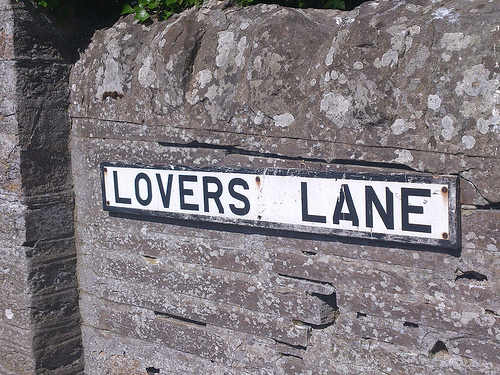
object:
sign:
[100, 161, 460, 250]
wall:
[66, 0, 499, 374]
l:
[109, 167, 135, 205]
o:
[133, 170, 155, 208]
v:
[153, 172, 177, 210]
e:
[176, 172, 202, 212]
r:
[199, 174, 226, 215]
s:
[225, 174, 251, 217]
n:
[364, 184, 397, 232]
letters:
[112, 170, 252, 214]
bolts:
[252, 174, 264, 183]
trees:
[114, 0, 211, 20]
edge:
[103, 161, 139, 172]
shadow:
[19, 9, 117, 66]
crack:
[153, 133, 249, 157]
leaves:
[107, 0, 191, 17]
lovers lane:
[111, 168, 439, 238]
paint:
[231, 217, 288, 231]